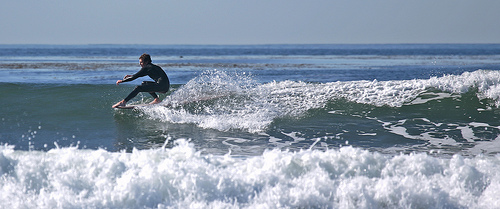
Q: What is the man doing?
A: Surfing.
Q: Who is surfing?
A: The man.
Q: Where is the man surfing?
A: The ocean.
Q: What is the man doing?
A: Balancing on the surfboard.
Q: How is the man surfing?
A: On the surfboard.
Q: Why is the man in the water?
A: The man is surfing.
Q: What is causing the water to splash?
A: The surfboard.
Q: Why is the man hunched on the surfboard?
A: He surfing.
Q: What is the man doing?
A: Surfing.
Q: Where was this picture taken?
A: The ocean.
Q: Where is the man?
A: On the surfboard.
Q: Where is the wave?
A: Behind the man.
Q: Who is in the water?
A: Surfer.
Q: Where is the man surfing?
A: In the ocean.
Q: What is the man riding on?
A: Surfboard.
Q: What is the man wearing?
A: Wetsuit.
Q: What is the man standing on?
A: Surfboard.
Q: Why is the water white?
A: Waves crashing.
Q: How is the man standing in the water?
A: On a surfboard.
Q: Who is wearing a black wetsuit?
A: Surfer.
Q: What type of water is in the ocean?
A: Saltwater.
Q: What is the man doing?
A: Surfing.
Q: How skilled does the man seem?
A: Professional.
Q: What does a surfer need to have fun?
A: Waves.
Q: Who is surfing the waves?
A: A man.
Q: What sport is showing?
A: Surfing.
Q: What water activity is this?
A: Surfing.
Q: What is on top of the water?
A: Sea foam.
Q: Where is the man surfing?
A: The ocean.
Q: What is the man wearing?
A: A wet suit.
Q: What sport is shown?
A: Surfing.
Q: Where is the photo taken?
A: Ocean.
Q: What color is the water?
A: Green.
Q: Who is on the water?
A: Surfer.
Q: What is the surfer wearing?
A: Wetsuit.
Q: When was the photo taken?
A: Daytime.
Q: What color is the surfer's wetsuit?
A: Black.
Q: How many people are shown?
A: One.